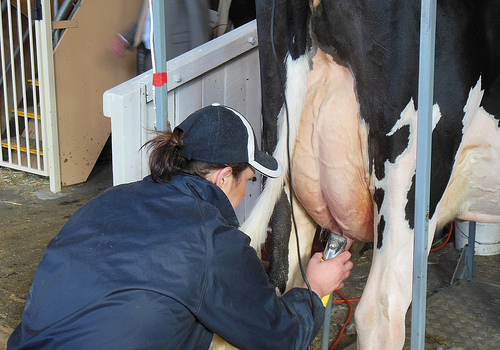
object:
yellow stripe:
[1, 142, 46, 157]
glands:
[290, 58, 384, 242]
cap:
[173, 102, 282, 180]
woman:
[7, 100, 352, 349]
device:
[314, 231, 349, 307]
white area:
[102, 20, 266, 228]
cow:
[237, 0, 500, 350]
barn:
[0, 0, 500, 350]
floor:
[0, 157, 499, 349]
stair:
[0, 135, 43, 158]